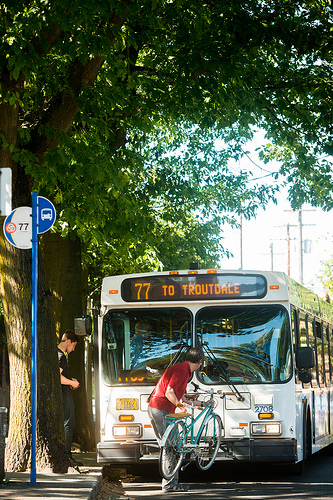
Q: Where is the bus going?
A: Troutdale.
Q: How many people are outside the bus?
A: Two.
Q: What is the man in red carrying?
A: A bike.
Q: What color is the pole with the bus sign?
A: Blue.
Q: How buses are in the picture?
A: One.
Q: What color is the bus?
A: White.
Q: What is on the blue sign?
A: A bus.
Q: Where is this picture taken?
A: Bus stop.